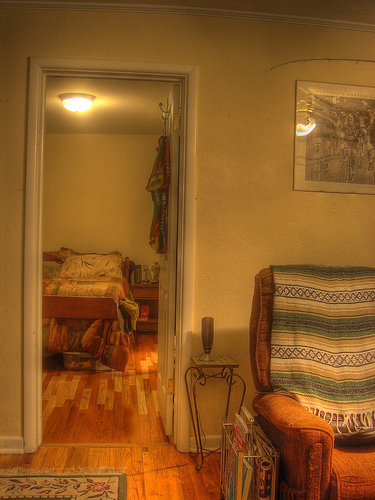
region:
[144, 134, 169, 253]
the clothes hanging on the door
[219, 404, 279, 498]
the magazine rack next to the chair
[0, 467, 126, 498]
the area rug on the ground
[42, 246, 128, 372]
the bed in the room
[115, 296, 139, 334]
the hats hanging off of the bed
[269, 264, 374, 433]
the blanket draped on the chair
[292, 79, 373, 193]
the picture hanging on the wall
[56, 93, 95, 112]
the light on the ceiling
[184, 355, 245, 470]
the table behind the chair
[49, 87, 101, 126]
light attached to ceiling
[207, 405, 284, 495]
wire book rack on side of chair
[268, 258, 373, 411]
blanket trown over the back of an armchair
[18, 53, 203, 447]
door to the bedroom open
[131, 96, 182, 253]
clothing hanging on hooks on the door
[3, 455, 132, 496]
area rug with floral pattern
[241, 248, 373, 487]
brown cushion arm chair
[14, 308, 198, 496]
light colored wood floor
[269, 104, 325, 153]
light reflecting on art work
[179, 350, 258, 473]
small table pushed up against the wall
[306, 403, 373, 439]
fringe on the bottom of the blanket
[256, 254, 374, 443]
blanket hanging over a chair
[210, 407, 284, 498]
magazine rack by a chair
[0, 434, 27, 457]
white trim on the bottom of the wall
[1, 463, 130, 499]
rug on the floor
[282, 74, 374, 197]
artwork hanging on the wall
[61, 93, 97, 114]
light on the ceiling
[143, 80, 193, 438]
door is open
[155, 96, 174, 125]
hook on the back of the door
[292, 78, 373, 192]
picture on wall under glass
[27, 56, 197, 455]
open door of bedroom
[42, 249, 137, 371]
comforter on top of bed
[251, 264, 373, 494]
front of brown chair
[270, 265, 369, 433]
striped blanket with fringe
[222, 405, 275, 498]
magazines inside of rack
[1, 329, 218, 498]
wood floor of two rooms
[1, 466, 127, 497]
corner of rug on floor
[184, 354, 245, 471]
table with curved legs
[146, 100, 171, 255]
clothes hanging on hook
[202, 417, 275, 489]
magazine rack by the sofa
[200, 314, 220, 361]
small vase on the table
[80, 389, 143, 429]
wood floor in the room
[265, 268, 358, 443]
blanket on the chair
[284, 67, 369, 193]
picture hanging on the wall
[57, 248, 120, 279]
pillow laying on the bed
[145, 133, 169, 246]
shirts hanging on the door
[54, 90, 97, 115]
light is on in the room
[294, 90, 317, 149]
reflection in the picture